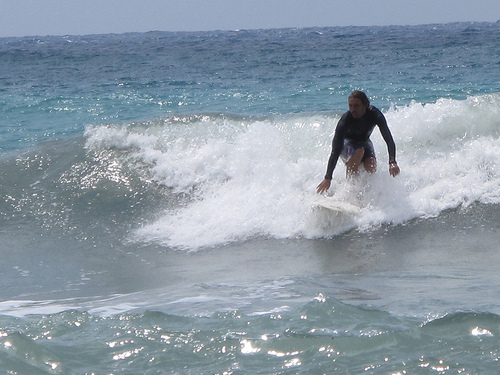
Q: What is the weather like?
A: It is clear.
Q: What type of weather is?
A: It is clear.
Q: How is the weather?
A: It is clear.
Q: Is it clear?
A: Yes, it is clear.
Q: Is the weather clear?
A: Yes, it is clear.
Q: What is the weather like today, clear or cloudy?
A: It is clear.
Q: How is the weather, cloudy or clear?
A: It is clear.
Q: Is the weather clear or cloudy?
A: It is clear.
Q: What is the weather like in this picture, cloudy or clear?
A: It is clear.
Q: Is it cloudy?
A: No, it is clear.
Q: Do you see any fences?
A: No, there are no fences.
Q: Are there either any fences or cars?
A: No, there are no fences or cars.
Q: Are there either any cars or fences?
A: No, there are no fences or cars.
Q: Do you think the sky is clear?
A: Yes, the sky is clear.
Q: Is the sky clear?
A: Yes, the sky is clear.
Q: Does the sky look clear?
A: Yes, the sky is clear.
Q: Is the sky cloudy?
A: No, the sky is clear.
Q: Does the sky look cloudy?
A: No, the sky is clear.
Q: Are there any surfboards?
A: Yes, there is a surfboard.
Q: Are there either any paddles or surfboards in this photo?
A: Yes, there is a surfboard.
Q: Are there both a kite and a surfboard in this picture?
A: No, there is a surfboard but no kites.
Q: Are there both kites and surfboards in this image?
A: No, there is a surfboard but no kites.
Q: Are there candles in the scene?
A: No, there are no candles.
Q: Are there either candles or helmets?
A: No, there are no candles or helmets.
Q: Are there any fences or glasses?
A: No, there are no fences or glasses.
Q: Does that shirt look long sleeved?
A: Yes, the shirt is long sleeved.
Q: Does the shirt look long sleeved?
A: Yes, the shirt is long sleeved.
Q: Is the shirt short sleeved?
A: No, the shirt is long sleeved.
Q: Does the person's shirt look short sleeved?
A: No, the shirt is long sleeved.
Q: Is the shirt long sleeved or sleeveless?
A: The shirt is long sleeved.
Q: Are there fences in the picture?
A: No, there are no fences.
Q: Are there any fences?
A: No, there are no fences.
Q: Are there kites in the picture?
A: No, there are no kites.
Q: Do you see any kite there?
A: No, there are no kites.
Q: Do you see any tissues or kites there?
A: No, there are no kites or tissues.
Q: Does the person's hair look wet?
A: Yes, the hair is wet.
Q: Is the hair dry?
A: No, the hair is wet.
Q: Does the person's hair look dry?
A: No, the hair is wet.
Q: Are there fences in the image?
A: No, there are no fences.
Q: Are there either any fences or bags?
A: No, there are no fences or bags.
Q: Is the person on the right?
A: Yes, the person is on the right of the image.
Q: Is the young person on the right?
A: Yes, the person is on the right of the image.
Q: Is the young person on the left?
A: No, the person is on the right of the image.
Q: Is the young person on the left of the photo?
A: No, the person is on the right of the image.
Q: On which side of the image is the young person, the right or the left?
A: The person is on the right of the image.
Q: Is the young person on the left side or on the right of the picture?
A: The person is on the right of the image.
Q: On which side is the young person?
A: The person is on the right of the image.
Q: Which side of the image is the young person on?
A: The person is on the right of the image.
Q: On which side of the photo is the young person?
A: The person is on the right of the image.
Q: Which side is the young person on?
A: The person is on the right of the image.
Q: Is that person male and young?
A: Yes, the person is male and young.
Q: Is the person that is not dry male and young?
A: Yes, the person is male and young.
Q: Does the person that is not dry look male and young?
A: Yes, the person is male and young.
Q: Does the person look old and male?
A: No, the person is male but young.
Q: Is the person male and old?
A: No, the person is male but young.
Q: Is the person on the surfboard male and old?
A: No, the person is male but young.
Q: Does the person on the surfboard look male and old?
A: No, the person is male but young.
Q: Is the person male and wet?
A: Yes, the person is male and wet.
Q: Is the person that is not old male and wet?
A: Yes, the person is male and wet.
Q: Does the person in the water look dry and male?
A: No, the person is male but wet.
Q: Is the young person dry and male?
A: No, the person is male but wet.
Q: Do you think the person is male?
A: Yes, the person is male.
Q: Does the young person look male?
A: Yes, the person is male.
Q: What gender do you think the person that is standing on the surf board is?
A: The person is male.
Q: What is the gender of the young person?
A: The person is male.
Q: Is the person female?
A: No, the person is male.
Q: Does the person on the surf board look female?
A: No, the person is male.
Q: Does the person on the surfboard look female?
A: No, the person is male.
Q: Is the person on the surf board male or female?
A: The person is male.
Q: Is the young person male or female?
A: The person is male.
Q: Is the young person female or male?
A: The person is male.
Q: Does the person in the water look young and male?
A: Yes, the person is young and male.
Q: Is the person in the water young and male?
A: Yes, the person is young and male.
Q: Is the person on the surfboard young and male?
A: Yes, the person is young and male.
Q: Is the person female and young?
A: No, the person is young but male.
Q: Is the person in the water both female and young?
A: No, the person is young but male.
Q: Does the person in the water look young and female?
A: No, the person is young but male.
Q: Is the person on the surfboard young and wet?
A: Yes, the person is young and wet.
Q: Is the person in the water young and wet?
A: Yes, the person is young and wet.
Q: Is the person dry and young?
A: No, the person is young but wet.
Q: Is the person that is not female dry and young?
A: No, the person is young but wet.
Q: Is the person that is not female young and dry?
A: No, the person is young but wet.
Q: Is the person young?
A: Yes, the person is young.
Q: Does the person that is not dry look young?
A: Yes, the person is young.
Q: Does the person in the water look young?
A: Yes, the person is young.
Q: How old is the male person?
A: The person is young.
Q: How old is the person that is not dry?
A: The person is young.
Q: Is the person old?
A: No, the person is young.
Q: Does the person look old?
A: No, the person is young.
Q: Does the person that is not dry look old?
A: No, the person is young.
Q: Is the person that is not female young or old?
A: The person is young.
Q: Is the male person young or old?
A: The person is young.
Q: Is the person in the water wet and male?
A: Yes, the person is wet and male.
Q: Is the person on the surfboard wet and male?
A: Yes, the person is wet and male.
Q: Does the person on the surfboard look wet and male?
A: Yes, the person is wet and male.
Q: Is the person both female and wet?
A: No, the person is wet but male.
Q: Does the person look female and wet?
A: No, the person is wet but male.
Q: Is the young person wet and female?
A: No, the person is wet but male.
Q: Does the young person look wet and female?
A: No, the person is wet but male.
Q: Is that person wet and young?
A: Yes, the person is wet and young.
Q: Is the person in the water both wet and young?
A: Yes, the person is wet and young.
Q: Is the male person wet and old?
A: No, the person is wet but young.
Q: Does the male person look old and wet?
A: No, the person is wet but young.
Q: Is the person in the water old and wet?
A: No, the person is wet but young.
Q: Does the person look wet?
A: Yes, the person is wet.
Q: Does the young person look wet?
A: Yes, the person is wet.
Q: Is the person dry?
A: No, the person is wet.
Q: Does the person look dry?
A: No, the person is wet.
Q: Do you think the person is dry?
A: No, the person is wet.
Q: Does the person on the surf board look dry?
A: No, the person is wet.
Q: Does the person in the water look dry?
A: No, the person is wet.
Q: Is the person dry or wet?
A: The person is wet.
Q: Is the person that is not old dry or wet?
A: The person is wet.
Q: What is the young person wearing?
A: The person is wearing a shirt.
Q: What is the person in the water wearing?
A: The person is wearing a shirt.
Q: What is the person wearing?
A: The person is wearing a shirt.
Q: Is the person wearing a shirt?
A: Yes, the person is wearing a shirt.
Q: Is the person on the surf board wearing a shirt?
A: Yes, the person is wearing a shirt.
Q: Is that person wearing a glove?
A: No, the person is wearing a shirt.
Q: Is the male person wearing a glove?
A: No, the person is wearing a shirt.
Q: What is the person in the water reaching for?
A: The person is reaching for the surfboard.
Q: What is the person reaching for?
A: The person is reaching for the surfboard.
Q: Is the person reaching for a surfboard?
A: Yes, the person is reaching for a surfboard.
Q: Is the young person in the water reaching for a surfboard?
A: Yes, the person is reaching for a surfboard.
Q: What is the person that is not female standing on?
A: The person is standing on the surfboard.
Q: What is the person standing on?
A: The person is standing on the surfboard.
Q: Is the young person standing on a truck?
A: No, the person is standing on the surf board.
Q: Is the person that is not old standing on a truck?
A: No, the person is standing on the surf board.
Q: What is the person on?
A: The person is on the surfboard.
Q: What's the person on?
A: The person is on the surfboard.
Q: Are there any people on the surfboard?
A: Yes, there is a person on the surfboard.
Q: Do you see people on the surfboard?
A: Yes, there is a person on the surfboard.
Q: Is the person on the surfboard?
A: Yes, the person is on the surfboard.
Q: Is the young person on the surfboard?
A: Yes, the person is on the surfboard.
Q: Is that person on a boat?
A: No, the person is on the surfboard.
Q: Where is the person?
A: The person is in the water.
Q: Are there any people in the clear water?
A: Yes, there is a person in the water.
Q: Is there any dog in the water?
A: No, there is a person in the water.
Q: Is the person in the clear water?
A: Yes, the person is in the water.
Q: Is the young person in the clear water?
A: Yes, the person is in the water.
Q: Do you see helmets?
A: No, there are no helmets.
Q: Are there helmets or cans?
A: No, there are no helmets or cans.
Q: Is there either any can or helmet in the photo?
A: No, there are no helmets or cans.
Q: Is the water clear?
A: Yes, the water is clear.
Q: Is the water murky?
A: No, the water is clear.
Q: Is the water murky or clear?
A: The water is clear.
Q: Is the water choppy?
A: Yes, the water is choppy.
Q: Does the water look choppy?
A: Yes, the water is choppy.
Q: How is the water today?
A: The water is choppy.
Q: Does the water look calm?
A: No, the water is choppy.